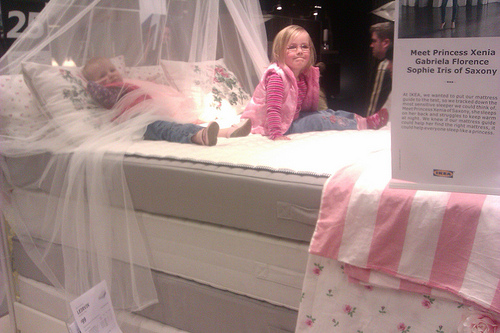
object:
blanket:
[308, 147, 500, 312]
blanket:
[297, 253, 499, 332]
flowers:
[342, 303, 356, 317]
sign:
[388, 0, 499, 196]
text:
[407, 49, 498, 75]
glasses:
[285, 44, 309, 51]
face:
[283, 33, 311, 69]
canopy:
[0, 0, 272, 320]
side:
[362, 21, 394, 117]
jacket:
[364, 56, 394, 118]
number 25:
[155, 122, 193, 151]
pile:
[0, 141, 438, 332]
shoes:
[367, 107, 389, 129]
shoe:
[226, 118, 251, 138]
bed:
[0, 58, 500, 332]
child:
[240, 25, 390, 141]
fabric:
[0, 0, 275, 323]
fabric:
[307, 117, 500, 292]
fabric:
[295, 258, 499, 332]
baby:
[81, 56, 252, 146]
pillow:
[159, 58, 251, 128]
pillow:
[21, 55, 126, 145]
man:
[362, 21, 395, 117]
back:
[260, 0, 393, 116]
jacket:
[240, 60, 320, 136]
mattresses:
[0, 146, 330, 244]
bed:
[15, 69, 368, 326]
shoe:
[200, 121, 219, 146]